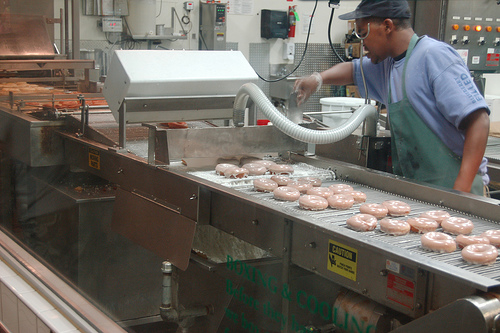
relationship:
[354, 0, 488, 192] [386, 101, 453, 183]
man in apron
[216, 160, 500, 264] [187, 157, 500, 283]
donuts on tray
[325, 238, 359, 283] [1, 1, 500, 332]
warning sticker on equipment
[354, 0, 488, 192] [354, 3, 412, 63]
man has head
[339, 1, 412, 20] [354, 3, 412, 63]
cap on head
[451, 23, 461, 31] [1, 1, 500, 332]
button on equipment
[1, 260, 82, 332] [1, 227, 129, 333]
tiles on window sill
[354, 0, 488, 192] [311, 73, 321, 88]
man wearing watch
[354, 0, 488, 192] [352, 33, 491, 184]
man wearing shirt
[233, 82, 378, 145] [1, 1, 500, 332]
hose attached to equipment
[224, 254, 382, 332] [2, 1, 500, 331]
writing on window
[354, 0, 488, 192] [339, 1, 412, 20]
man wearing cap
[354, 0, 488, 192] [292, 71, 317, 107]
man has hand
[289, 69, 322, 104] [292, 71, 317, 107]
glove on hand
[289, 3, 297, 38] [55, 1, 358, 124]
fire extinguisher on wall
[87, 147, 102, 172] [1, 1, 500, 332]
warning sticker on equipment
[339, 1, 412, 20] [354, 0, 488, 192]
cap on man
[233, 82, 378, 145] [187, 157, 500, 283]
hose over tray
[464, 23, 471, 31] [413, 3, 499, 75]
button on box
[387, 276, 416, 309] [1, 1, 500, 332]
sign on equipment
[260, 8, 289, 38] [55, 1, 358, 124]
box on wall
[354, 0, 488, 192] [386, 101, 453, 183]
man wearing apron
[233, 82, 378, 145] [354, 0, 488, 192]
hose near man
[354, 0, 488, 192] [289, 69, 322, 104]
man wearing glove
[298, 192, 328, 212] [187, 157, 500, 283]
donut on tray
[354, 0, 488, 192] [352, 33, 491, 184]
man in shirt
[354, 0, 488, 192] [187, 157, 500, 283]
man by tray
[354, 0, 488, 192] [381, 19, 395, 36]
man has ear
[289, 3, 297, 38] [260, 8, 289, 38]
fire extinguisher next to box